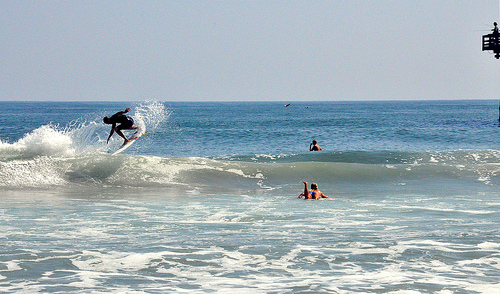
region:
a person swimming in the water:
[297, 173, 334, 211]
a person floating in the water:
[307, 138, 325, 159]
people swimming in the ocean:
[292, 137, 330, 208]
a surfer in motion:
[62, 108, 160, 176]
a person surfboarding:
[88, 95, 156, 167]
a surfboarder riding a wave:
[75, 100, 162, 168]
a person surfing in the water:
[90, 104, 164, 166]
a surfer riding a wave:
[88, 103, 160, 171]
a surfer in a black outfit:
[95, 110, 153, 162]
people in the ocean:
[91, 108, 331, 209]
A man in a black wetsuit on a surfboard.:
[102, 105, 142, 144]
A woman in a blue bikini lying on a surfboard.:
[297, 180, 326, 200]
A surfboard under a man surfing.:
[108, 124, 148, 155]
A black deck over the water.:
[481, 31, 499, 50]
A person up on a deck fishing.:
[491, 20, 499, 33]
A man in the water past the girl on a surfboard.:
[308, 137, 320, 153]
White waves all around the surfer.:
[3, 97, 172, 193]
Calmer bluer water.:
[1, 100, 499, 147]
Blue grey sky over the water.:
[0, 2, 499, 97]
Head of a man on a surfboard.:
[101, 115, 111, 124]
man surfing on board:
[93, 100, 141, 175]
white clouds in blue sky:
[205, 26, 242, 53]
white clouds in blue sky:
[224, 31, 259, 71]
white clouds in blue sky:
[373, 41, 415, 67]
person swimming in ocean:
[293, 160, 333, 210]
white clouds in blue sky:
[82, 25, 144, 67]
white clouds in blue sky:
[248, 39, 290, 73]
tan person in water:
[291, 170, 363, 204]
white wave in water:
[239, 230, 328, 274]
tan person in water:
[306, 128, 338, 155]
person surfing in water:
[93, 110, 177, 152]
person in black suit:
[96, 108, 177, 161]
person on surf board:
[84, 95, 169, 180]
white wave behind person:
[129, 95, 164, 140]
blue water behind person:
[216, 105, 395, 165]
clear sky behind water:
[214, 32, 371, 104]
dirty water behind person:
[223, 167, 323, 248]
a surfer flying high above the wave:
[99, 106, 138, 148]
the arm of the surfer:
[105, 120, 117, 142]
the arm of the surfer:
[116, 108, 130, 113]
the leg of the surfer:
[115, 121, 131, 143]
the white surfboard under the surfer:
[107, 123, 146, 153]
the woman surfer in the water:
[296, 183, 323, 203]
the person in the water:
[307, 139, 318, 152]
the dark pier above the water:
[479, 30, 498, 45]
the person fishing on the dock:
[475, 20, 499, 33]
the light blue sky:
[1, 2, 498, 102]